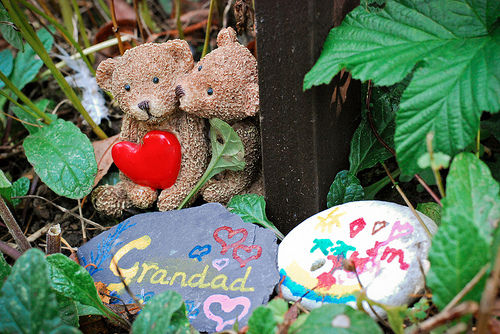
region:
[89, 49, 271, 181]
two stuffed animals in the leaves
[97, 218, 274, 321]
blue stone with writing on it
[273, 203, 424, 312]
white stone next to blue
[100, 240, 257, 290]
word grandad written on stone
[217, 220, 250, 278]
two red hearts on the stone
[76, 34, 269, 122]
teddy bear is kissing other bear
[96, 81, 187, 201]
bear holding a red heart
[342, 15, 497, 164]
a large green leaf overhanging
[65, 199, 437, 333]
two painted stones on the ground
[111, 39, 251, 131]
teddy bears are brown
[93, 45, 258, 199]
Two teddy bear kept near the grass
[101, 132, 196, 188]
Red color heart symbol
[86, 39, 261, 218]
Brown color teddy bears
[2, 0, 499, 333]
Green color leaves with grass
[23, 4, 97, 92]
Green color grass near the teddy bears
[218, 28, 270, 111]
Ears of the teddy bear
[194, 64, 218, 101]
Eyes of the teddy bear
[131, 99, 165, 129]
Black color nose and mouth of the teddy bear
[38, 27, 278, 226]
Teddy bears kept in the dirt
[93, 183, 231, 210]
Legs of the teddy bear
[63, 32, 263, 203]
two teddy bears with heart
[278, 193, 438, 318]
rock with designs on ground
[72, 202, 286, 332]
rock with writing and hearts on ground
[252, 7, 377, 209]
wooden post in ground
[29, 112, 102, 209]
green leaf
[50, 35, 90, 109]
two grass leafs in ground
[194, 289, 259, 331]
pink heart on rock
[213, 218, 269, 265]
two red hearts on rock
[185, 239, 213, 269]
blue heart on rock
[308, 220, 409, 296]
picture on rock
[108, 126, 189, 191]
Red heart on bear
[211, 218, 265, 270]
Red hearts on rock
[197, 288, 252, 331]
Pink heart on rock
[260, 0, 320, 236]
Brown post next to bears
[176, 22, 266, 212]
Bear kissing other bear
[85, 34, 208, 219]
Bear being kissed by other bear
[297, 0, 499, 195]
Green leaves of plant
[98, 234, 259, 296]
Word "Grandad" written in yellow on rock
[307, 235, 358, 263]
Blue writing on stone